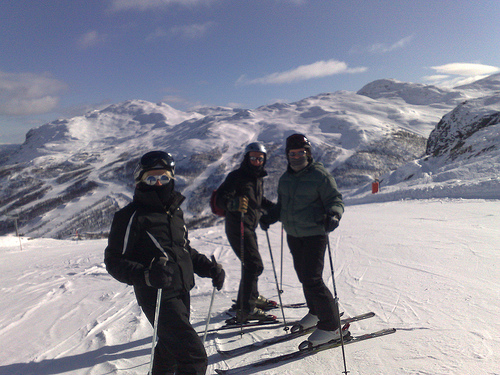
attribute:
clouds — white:
[64, 20, 209, 52]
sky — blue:
[3, 5, 490, 114]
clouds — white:
[136, 41, 183, 97]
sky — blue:
[2, 2, 497, 71]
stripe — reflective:
[119, 208, 141, 255]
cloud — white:
[260, 62, 349, 87]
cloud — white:
[6, 69, 55, 113]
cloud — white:
[365, 35, 419, 55]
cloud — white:
[83, 26, 221, 43]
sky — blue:
[24, 20, 477, 107]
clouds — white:
[40, 36, 86, 75]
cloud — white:
[76, 29, 98, 45]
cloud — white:
[0, 66, 64, 116]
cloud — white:
[238, 56, 365, 86]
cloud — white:
[428, 60, 498, 76]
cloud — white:
[145, 17, 215, 37]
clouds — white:
[3, 69, 65, 116]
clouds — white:
[235, 56, 366, 87]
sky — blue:
[78, 5, 406, 69]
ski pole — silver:
[142, 290, 159, 372]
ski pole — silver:
[192, 285, 213, 342]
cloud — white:
[2, 65, 67, 121]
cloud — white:
[60, 102, 106, 114]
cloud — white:
[47, 26, 117, 56]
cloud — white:
[102, 0, 217, 21]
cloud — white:
[227, 52, 372, 89]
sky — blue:
[0, 0, 497, 143]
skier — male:
[255, 127, 351, 350]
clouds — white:
[5, 0, 485, 112]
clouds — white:
[231, 43, 412, 110]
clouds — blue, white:
[249, 51, 499, 82]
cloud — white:
[362, 38, 411, 53]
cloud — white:
[242, 57, 365, 82]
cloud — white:
[5, 72, 48, 119]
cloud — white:
[72, 25, 105, 57]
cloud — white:
[140, 25, 228, 53]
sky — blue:
[0, 6, 500, 135]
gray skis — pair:
[238, 295, 397, 372]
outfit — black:
[201, 155, 287, 308]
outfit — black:
[100, 181, 231, 370]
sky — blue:
[4, 1, 484, 189]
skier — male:
[214, 143, 276, 328]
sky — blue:
[4, 2, 484, 167]